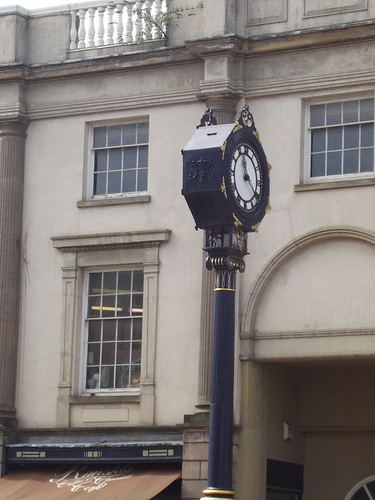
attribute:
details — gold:
[218, 174, 229, 199]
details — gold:
[217, 138, 228, 161]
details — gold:
[229, 118, 244, 132]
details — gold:
[249, 127, 263, 146]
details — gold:
[263, 156, 273, 176]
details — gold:
[261, 195, 272, 214]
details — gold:
[249, 218, 263, 234]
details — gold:
[229, 209, 245, 228]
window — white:
[77, 268, 144, 400]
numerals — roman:
[236, 191, 251, 210]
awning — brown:
[8, 465, 180, 498]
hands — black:
[239, 152, 263, 201]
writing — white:
[44, 463, 145, 497]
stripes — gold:
[198, 485, 235, 497]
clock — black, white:
[166, 103, 280, 246]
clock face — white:
[228, 142, 264, 212]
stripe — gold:
[211, 286, 236, 291]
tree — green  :
[127, 6, 172, 38]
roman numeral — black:
[242, 145, 249, 153]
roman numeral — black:
[250, 152, 256, 159]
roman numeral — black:
[254, 164, 260, 170]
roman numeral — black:
[254, 178, 262, 187]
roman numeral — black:
[252, 191, 261, 201]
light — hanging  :
[88, 295, 129, 316]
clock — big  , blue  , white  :
[210, 118, 279, 233]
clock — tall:
[184, 102, 270, 497]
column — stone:
[197, 249, 213, 441]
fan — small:
[84, 364, 112, 396]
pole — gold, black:
[204, 252, 235, 495]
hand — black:
[240, 151, 249, 179]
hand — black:
[243, 173, 259, 199]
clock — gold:
[180, 114, 273, 234]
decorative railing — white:
[70, 0, 166, 51]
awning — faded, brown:
[8, 459, 182, 497]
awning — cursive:
[16, 429, 211, 498]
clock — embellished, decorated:
[180, 105, 277, 269]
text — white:
[44, 466, 143, 493]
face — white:
[226, 139, 269, 211]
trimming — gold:
[196, 484, 238, 498]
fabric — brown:
[5, 475, 148, 498]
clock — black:
[227, 140, 264, 215]